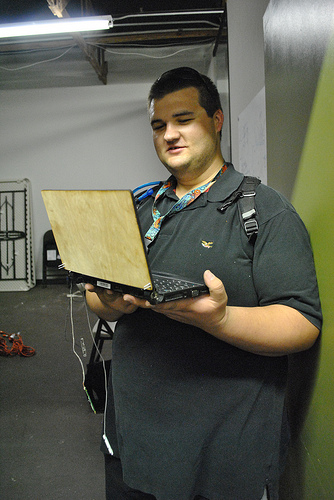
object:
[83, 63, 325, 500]
man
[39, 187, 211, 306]
laptop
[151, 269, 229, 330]
hands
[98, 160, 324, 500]
shirt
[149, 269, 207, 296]
keyboard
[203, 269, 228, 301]
thumb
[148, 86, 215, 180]
face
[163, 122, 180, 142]
nose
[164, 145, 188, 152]
mouth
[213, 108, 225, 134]
ear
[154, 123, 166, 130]
eyes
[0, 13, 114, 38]
light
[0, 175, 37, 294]
table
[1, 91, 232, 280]
wall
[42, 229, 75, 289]
chair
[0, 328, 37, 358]
chord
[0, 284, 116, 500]
ground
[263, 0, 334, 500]
wall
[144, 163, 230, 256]
lanyard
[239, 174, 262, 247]
strap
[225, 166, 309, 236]
shoulder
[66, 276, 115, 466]
chord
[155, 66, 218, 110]
sunglasses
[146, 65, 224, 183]
head